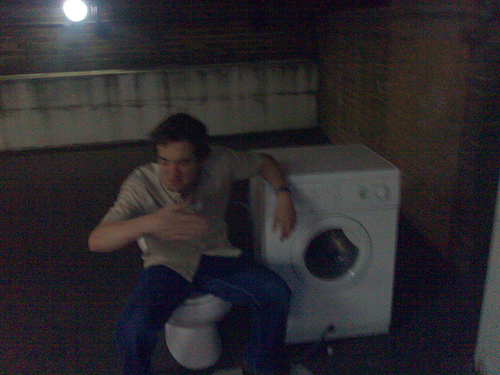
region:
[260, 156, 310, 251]
forearm and wrist with dark band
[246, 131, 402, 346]
white appliance with window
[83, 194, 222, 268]
hand,elbow and forearm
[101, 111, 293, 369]
man in light colored shirt and blue jeans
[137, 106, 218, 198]
head of dark haired man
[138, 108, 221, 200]
dark haired man making a face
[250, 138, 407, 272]
arm resting on an appliance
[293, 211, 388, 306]
windowed door of an appliance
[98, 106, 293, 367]
man sitting on toilet with pants up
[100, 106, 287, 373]
man wearing blue jeans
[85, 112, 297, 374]
a dressed man sitting on a toilet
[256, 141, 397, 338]
a front load washing machine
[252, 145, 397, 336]
a front load dryer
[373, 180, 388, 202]
the washing machines control knob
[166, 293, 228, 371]
a white porcelain toilet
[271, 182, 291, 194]
the man is wearing a wrist watch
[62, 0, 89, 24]
a light source on the wall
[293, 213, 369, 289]
the viewing window of the washing machine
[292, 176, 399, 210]
the control panel on the dryer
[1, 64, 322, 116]
a cement wall behind the man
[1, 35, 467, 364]
the picture is a little blurry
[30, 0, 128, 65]
the light is on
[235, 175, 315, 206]
the man os wearing a watch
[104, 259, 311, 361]
the man is wearing jeans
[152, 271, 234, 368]
a toilet on the floor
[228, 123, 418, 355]
man leaning on the washing machine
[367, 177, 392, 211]
knob on the washing machine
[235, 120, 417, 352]
the washing machine is white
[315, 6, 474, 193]
the wall is made of bricks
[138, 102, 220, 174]
the man has dark hair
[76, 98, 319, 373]
a man sitting on a toilet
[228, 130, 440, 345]
a washing machine next to a toilet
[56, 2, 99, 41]
a single white bulb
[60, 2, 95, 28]
the light is turned on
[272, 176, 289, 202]
a watch on the man's wrist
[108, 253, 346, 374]
blue jeans on a man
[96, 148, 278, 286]
tan shirt on a man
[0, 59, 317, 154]
white concrete strip on wall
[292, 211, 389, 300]
round door to washing machine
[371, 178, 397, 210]
white knob on washing machine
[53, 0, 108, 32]
Light in the background.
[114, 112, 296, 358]
Man on a toilet.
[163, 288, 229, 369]
Man on a toilet.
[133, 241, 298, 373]
Man is wearing jeans.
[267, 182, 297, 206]
The man is wearing a watch.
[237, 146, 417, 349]
Dryer next to the man.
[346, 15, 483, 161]
The wall is brick.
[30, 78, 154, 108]
Dark on the cement.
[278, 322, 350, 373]
Cord to the dryer.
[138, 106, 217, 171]
The man has brown hair.